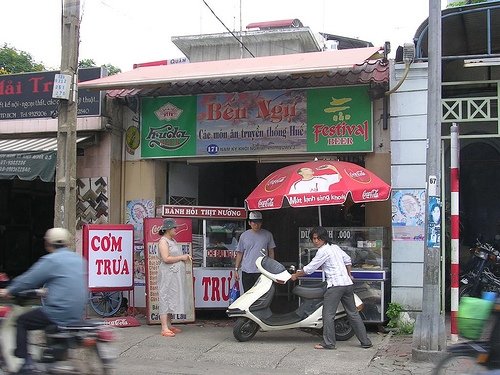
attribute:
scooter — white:
[224, 242, 368, 344]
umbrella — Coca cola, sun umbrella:
[232, 149, 408, 222]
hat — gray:
[160, 216, 180, 232]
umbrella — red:
[237, 154, 394, 226]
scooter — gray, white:
[225, 247, 365, 348]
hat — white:
[247, 212, 264, 222]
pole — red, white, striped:
[450, 125, 458, 342]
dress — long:
[162, 262, 184, 294]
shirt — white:
[299, 241, 352, 283]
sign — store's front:
[145, 85, 374, 152]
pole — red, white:
[424, 0, 443, 372]